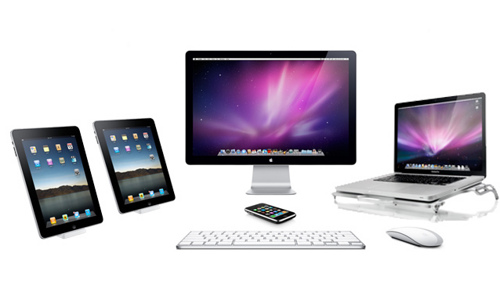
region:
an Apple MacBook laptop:
[334, 91, 487, 202]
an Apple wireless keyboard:
[178, 225, 364, 252]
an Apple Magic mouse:
[386, 225, 443, 249]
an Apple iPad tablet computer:
[92, 114, 177, 216]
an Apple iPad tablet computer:
[8, 124, 105, 238]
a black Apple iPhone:
[243, 202, 295, 222]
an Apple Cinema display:
[183, 48, 359, 198]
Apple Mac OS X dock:
[213, 146, 325, 156]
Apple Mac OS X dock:
[402, 160, 470, 172]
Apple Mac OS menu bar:
[191, 56, 350, 60]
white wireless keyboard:
[185, 216, 362, 256]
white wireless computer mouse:
[380, 227, 455, 249]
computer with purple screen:
[180, 55, 355, 160]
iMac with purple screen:
[182, 46, 352, 191]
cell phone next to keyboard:
[243, 197, 302, 227]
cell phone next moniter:
[242, 197, 301, 221]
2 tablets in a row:
[11, 110, 178, 243]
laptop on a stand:
[341, 97, 496, 219]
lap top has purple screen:
[390, 102, 495, 177]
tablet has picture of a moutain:
[10, 129, 103, 240]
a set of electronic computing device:
[10, 45, 499, 255]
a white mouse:
[379, 223, 447, 250]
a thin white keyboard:
[176, 227, 365, 253]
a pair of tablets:
[12, 115, 176, 239]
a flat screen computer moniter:
[185, 50, 357, 198]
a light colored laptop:
[332, 91, 499, 222]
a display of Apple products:
[12, 46, 499, 251]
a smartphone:
[246, 202, 296, 223]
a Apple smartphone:
[243, 201, 297, 222]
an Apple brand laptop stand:
[332, 184, 498, 219]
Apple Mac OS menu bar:
[395, 95, 482, 110]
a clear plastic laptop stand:
[332, 182, 499, 220]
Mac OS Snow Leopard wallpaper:
[189, 60, 348, 158]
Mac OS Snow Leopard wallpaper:
[396, 96, 484, 172]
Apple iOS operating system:
[100, 119, 170, 205]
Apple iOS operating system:
[16, 133, 94, 227]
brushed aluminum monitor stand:
[243, 164, 295, 196]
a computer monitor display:
[184, 45, 358, 197]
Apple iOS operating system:
[249, 201, 284, 216]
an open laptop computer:
[332, 89, 486, 203]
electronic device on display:
[11, 115, 106, 247]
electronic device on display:
[93, 121, 168, 211]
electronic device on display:
[169, 40, 354, 210]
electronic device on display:
[381, 104, 486, 223]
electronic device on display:
[252, 200, 293, 229]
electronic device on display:
[178, 220, 365, 256]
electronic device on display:
[394, 219, 444, 260]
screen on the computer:
[203, 53, 343, 154]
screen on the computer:
[399, 104, 487, 181]